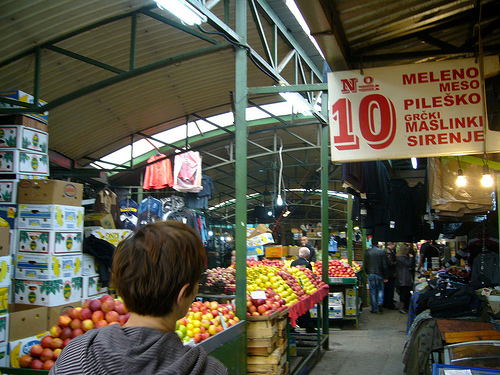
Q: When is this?
A: Night time.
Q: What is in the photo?
A: Fruits.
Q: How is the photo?
A: Clear.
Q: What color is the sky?
A: Gray.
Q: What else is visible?
A: Stalls.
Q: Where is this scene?
A: Warehouse.